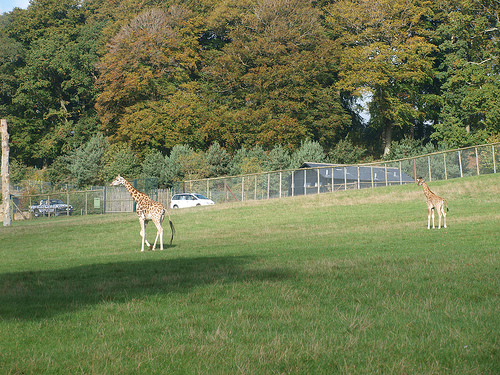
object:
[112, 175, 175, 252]
giraffe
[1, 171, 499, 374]
field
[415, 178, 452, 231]
giraffe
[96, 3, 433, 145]
leaves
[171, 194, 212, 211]
car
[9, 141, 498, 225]
fence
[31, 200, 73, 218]
truck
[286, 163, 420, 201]
building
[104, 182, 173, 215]
fence gates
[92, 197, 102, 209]
sign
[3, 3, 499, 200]
trees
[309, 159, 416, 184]
roof